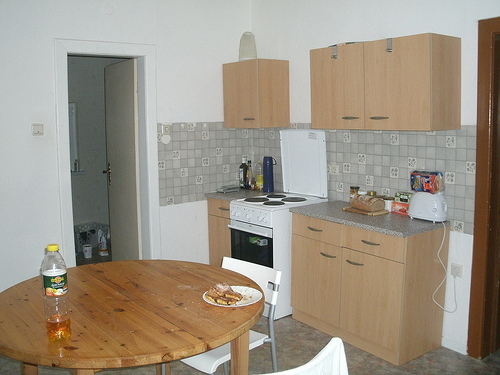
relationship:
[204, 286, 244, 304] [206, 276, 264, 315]
food on plate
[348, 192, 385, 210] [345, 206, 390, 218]
bread on board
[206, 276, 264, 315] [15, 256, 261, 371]
plate on table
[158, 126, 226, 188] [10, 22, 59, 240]
tiles on wall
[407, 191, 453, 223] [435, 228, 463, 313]
toaster has cord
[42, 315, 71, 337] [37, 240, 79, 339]
liquid in bottle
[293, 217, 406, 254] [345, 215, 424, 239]
drawers under counter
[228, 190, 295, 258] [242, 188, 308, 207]
stove has burners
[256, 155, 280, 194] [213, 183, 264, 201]
thermos on counter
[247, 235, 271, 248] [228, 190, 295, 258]
box in oven